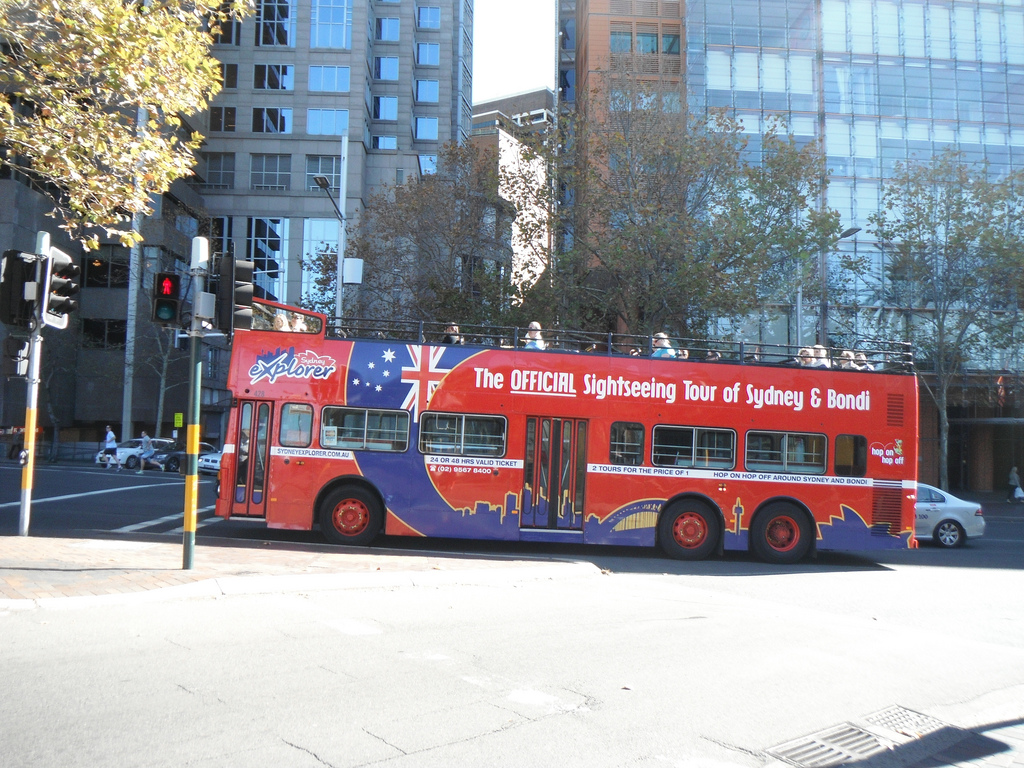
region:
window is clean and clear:
[304, 108, 356, 141]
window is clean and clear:
[250, 104, 298, 130]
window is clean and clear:
[256, 3, 299, 51]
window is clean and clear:
[302, 1, 350, 50]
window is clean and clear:
[377, 17, 400, 41]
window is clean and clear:
[376, 55, 399, 78]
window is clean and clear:
[377, 90, 400, 117]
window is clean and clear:
[373, 134, 399, 153]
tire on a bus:
[743, 494, 841, 577]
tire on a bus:
[629, 485, 734, 572]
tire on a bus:
[305, 452, 413, 569]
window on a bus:
[642, 413, 750, 474]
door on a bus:
[512, 403, 599, 550]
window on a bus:
[307, 400, 422, 461]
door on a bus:
[223, 389, 266, 544]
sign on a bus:
[240, 337, 352, 433]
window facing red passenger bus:
[710, 48, 733, 91]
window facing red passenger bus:
[730, 48, 757, 93]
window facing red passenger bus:
[787, 48, 816, 93]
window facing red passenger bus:
[734, 110, 763, 135]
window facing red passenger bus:
[765, 112, 792, 135]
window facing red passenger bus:
[788, 110, 815, 137]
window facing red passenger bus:
[821, 112, 852, 157]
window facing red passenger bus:
[849, 115, 881, 160]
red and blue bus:
[216, 299, 931, 562]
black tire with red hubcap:
[316, 477, 384, 553]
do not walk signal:
[151, 268, 186, 327]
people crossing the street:
[95, 422, 173, 481]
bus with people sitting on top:
[211, 298, 919, 564]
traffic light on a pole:
[180, 229, 257, 568]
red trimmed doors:
[522, 412, 592, 539]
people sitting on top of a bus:
[218, 290, 927, 563]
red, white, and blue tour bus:
[211, 299, 923, 572]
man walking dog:
[89, 422, 131, 476]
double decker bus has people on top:
[213, 292, 921, 562]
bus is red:
[213, 296, 919, 559]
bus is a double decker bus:
[213, 292, 921, 565]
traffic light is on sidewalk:
[150, 232, 252, 568]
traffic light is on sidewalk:
[0, 223, 78, 534]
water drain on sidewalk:
[768, 700, 974, 764]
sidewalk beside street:
[0, 529, 1023, 763]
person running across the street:
[131, 431, 163, 473]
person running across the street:
[104, 421, 121, 469]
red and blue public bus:
[211, 318, 924, 568]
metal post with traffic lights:
[142, 226, 261, 582]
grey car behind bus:
[215, 318, 994, 575]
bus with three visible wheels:
[215, 314, 917, 564]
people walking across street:
[95, 416, 173, 486]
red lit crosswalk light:
[149, 262, 191, 342]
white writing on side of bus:
[203, 312, 930, 582]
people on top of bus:
[218, 286, 917, 575]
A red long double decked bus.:
[192, 304, 964, 599]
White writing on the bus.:
[462, 356, 887, 426]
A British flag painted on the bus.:
[325, 332, 488, 428]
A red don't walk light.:
[142, 255, 190, 345]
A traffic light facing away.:
[211, 243, 265, 354]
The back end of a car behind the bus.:
[893, 470, 985, 560]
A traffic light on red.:
[41, 236, 92, 341]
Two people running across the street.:
[82, 407, 165, 484]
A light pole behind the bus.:
[307, 124, 369, 343]